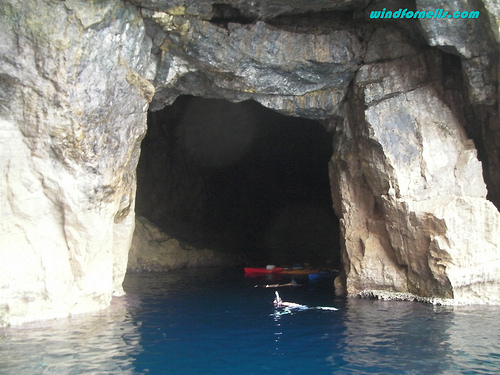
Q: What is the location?
A: A cave.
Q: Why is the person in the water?
A: Snorkeling.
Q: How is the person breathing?
A: Snorkel.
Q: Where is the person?
A: In the water.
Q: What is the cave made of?
A: Stone.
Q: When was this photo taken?
A: Day time.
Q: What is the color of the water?
A: Blue.